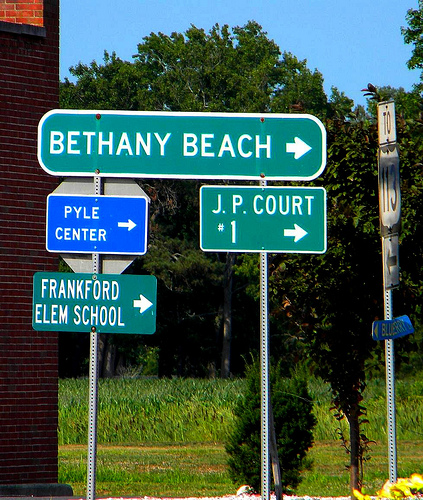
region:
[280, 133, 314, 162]
An arrow pointing right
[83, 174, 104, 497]
Gray post holding up signs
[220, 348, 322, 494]
A small green bush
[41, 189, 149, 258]
A blue and white sign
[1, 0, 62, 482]
Bricks on a building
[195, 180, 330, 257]
A rectangle shaped sign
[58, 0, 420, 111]
A clear and blue sky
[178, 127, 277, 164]
The word "BEACH" on a sign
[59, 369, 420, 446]
The grass is very long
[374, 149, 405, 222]
Number 113 on a sign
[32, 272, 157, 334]
A green and white sign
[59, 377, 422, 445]
A feild in the distance.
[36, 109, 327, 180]
A large green sign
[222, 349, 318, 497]
A green bush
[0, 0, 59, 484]
A brick wall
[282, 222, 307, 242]
A white arrow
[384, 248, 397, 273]
A black arrow pointing left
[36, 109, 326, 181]
A sign pointing towards a beach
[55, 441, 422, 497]
A patch of grass in the distance.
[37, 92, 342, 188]
green and white sign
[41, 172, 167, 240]
blue and white sign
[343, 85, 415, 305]
black and white sign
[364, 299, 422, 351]
blue street sign under road sign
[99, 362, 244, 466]
green crops under signs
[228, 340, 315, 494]
small green bush behind sign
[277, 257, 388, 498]
green tree right of bush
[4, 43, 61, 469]
building to left of signs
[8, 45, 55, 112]
building is red brick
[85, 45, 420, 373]
tall trees in background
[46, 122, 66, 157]
The letter is white.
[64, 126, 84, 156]
The letter is white.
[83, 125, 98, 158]
The letter is white.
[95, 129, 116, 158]
The letter is white.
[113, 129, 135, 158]
The letter is white.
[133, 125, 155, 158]
The letter is white.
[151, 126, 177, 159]
The letter is white.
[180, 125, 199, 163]
The letter is white.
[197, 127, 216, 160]
The letter is white.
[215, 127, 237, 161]
The letter is white.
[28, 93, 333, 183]
The corners of the sign are rounded.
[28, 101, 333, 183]
The sign has a white arrow on it.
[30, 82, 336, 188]
The arrow is pointing to the right.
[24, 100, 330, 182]
The sign is green and white.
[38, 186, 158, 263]
The sign is blue and white.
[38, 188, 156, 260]
The sign has an arrow on it.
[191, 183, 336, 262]
The sign has an arrow on it.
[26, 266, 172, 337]
The sign has an arrow on it.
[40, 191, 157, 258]
The arrow is pointing to the right.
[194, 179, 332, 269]
The arrow is pointing to the right.